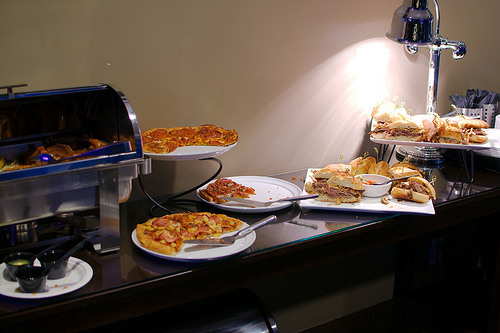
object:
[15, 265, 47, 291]
bowl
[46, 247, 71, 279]
bowl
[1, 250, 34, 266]
bowl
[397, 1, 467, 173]
light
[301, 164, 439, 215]
plate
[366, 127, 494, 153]
plate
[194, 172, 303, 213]
plate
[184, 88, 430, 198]
wall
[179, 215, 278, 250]
knife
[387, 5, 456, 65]
warming light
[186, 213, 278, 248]
silver server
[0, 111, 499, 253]
food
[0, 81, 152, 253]
tray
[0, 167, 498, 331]
table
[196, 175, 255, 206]
pizza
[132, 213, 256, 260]
plate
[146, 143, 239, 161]
plate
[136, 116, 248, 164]
slices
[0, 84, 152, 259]
oven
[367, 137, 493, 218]
ground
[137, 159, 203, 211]
wires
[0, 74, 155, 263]
tool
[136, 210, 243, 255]
pizza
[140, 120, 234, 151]
pizza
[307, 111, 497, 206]
sandwich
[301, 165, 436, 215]
platter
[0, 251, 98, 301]
plate